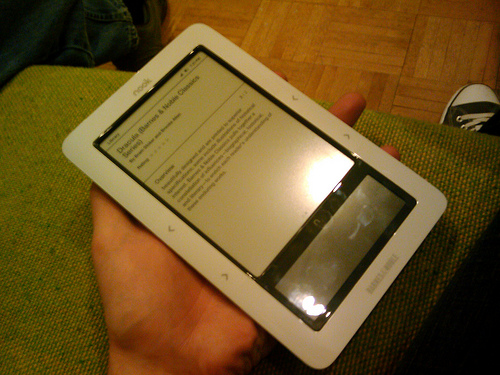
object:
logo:
[363, 251, 400, 294]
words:
[150, 159, 178, 186]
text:
[103, 56, 273, 212]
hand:
[86, 91, 398, 374]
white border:
[60, 20, 447, 371]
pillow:
[0, 63, 499, 374]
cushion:
[0, 65, 499, 374]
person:
[90, 83, 500, 375]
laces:
[454, 110, 496, 132]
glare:
[296, 293, 327, 316]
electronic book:
[57, 21, 447, 371]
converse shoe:
[436, 81, 498, 133]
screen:
[91, 44, 419, 333]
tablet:
[60, 21, 448, 371]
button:
[160, 219, 179, 234]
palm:
[89, 221, 269, 374]